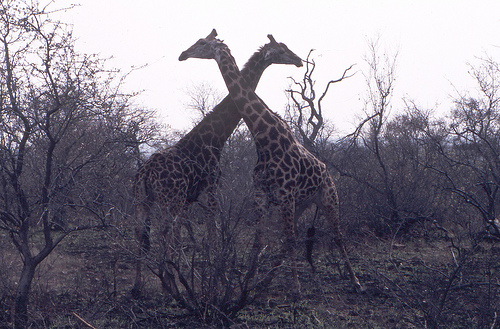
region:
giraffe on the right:
[171, 20, 366, 301]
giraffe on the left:
[113, 32, 308, 315]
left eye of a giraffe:
[196, 38, 206, 48]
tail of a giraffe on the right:
[305, 203, 321, 273]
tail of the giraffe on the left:
[132, 218, 153, 252]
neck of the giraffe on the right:
[216, 58, 271, 130]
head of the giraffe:
[239, 27, 325, 92]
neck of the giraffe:
[217, 62, 281, 137]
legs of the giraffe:
[233, 189, 375, 279]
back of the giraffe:
[108, 134, 201, 250]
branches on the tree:
[42, 82, 129, 174]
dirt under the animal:
[371, 248, 431, 305]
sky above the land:
[101, 11, 174, 53]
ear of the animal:
[250, 42, 280, 72]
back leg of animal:
[312, 179, 369, 309]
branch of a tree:
[1, 241, 60, 316]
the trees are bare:
[291, 62, 492, 262]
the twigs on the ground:
[362, 232, 469, 324]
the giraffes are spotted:
[145, 30, 333, 297]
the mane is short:
[239, 47, 259, 84]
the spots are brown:
[263, 126, 308, 198]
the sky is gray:
[288, 13, 461, 120]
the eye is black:
[201, 38, 208, 48]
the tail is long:
[139, 170, 161, 246]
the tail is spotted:
[137, 167, 172, 282]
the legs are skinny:
[251, 187, 358, 317]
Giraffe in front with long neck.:
[178, 20, 374, 302]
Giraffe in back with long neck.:
[132, 25, 382, 317]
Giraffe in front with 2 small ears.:
[130, 25, 375, 320]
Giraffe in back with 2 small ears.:
[125, 20, 365, 320]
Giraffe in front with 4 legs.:
[176, 29, 385, 299]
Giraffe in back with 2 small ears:
[122, 6, 380, 324]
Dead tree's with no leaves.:
[5, 1, 497, 327]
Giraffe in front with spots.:
[128, 8, 368, 327]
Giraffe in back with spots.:
[131, 14, 366, 325]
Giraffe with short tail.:
[118, 23, 368, 323]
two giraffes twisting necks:
[120, 25, 368, 307]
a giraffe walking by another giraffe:
[175, 26, 375, 293]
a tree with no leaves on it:
[0, 8, 150, 323]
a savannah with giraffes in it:
[10, 20, 490, 286]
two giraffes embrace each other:
[130, 26, 355, 291]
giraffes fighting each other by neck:
[115, 25, 365, 297]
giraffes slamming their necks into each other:
[172, 16, 302, 226]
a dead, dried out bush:
[137, 200, 287, 316]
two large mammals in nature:
[130, 32, 360, 287]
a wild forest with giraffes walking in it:
[7, 10, 485, 315]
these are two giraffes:
[27, 15, 395, 256]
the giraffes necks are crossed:
[134, 24, 479, 308]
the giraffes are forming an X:
[122, 25, 314, 173]